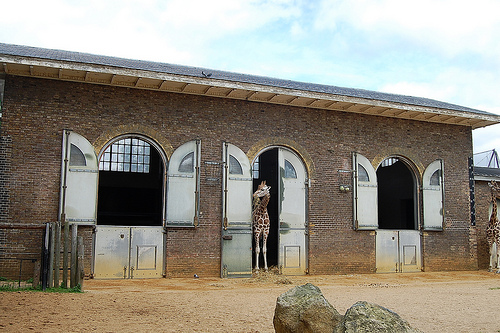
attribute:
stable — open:
[58, 127, 200, 280]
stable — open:
[218, 137, 315, 276]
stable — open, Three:
[352, 150, 443, 272]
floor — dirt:
[82, 276, 241, 295]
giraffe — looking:
[235, 167, 322, 252]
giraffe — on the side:
[246, 177, 276, 270]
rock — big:
[267, 279, 400, 331]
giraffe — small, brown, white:
[252, 178, 272, 274]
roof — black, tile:
[0, 43, 499, 134]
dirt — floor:
[390, 287, 469, 332]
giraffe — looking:
[255, 179, 270, 274]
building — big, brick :
[48, 47, 396, 229]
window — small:
[93, 132, 152, 174]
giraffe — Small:
[244, 177, 289, 282]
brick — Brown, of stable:
[3, 76, 476, 270]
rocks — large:
[271, 280, 420, 330]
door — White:
[342, 137, 463, 299]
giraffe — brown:
[249, 177, 274, 274]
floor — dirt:
[117, 277, 492, 284]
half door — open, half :
[345, 148, 385, 235]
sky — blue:
[0, 0, 485, 154]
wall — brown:
[3, 72, 485, 272]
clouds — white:
[4, 2, 181, 65]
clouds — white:
[157, 0, 301, 47]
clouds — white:
[305, 0, 485, 62]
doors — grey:
[53, 130, 106, 225]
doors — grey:
[159, 134, 204, 229]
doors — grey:
[216, 140, 256, 278]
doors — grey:
[270, 146, 311, 276]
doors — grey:
[347, 144, 381, 233]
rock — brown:
[271, 278, 345, 331]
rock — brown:
[340, 294, 413, 331]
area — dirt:
[0, 272, 499, 333]